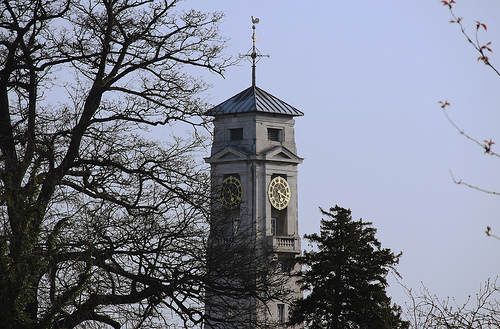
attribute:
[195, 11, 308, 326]
clock tower — gray 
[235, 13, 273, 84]
rod — decorative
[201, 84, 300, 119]
roof — blue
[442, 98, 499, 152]
branch — skinny 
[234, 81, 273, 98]
spot — black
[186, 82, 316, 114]
roof — blue 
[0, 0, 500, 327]
sky — light blue, blue, clear 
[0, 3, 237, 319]
tree — bare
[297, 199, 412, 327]
tree — green 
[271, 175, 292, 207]
face — white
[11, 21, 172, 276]
branches — brown tree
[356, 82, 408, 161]
sky — clear light blue 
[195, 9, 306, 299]
tower — round clock 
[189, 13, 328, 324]
tower — tall gray clock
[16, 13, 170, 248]
branches — thin brown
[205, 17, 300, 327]
tower — clock 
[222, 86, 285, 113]
roof — blue 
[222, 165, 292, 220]
clock — other side